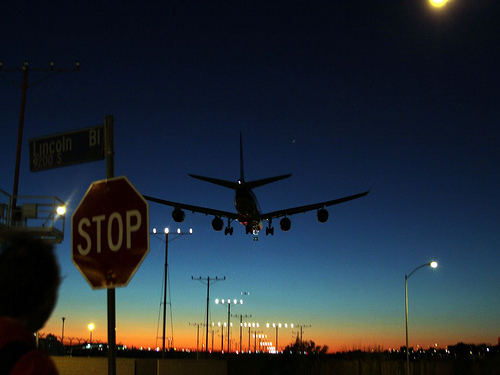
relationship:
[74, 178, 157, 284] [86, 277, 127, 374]
stop sign on top of pole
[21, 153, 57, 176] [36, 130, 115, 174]
numbers under street sign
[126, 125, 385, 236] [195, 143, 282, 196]
plane has tail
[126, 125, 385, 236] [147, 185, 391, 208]
plane has wings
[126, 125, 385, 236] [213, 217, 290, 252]
plane has wheels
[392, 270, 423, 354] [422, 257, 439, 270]
light pole has street light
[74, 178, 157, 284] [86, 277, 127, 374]
stop sign on pole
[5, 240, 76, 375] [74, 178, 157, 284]
person near stop sign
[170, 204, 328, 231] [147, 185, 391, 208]
engines under wings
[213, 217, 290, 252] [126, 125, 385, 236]
wheels under plane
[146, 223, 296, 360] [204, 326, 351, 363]
street lights part of runway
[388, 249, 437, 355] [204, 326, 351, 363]
street light near runway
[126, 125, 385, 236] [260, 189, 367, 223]
plane has wing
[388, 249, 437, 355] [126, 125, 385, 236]
street light under plane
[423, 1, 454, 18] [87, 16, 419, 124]
moon sits in sky